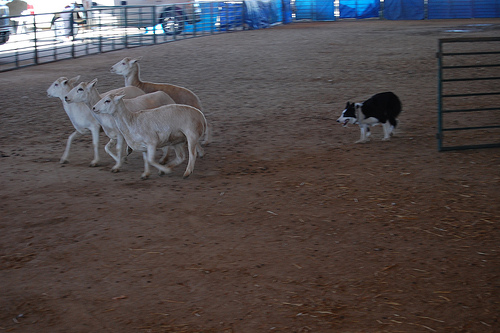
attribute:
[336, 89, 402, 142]
dog — black, white, compacted, herding sheep, herding, sheepdog, running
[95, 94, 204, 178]
sheep — running, in group, being herded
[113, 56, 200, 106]
sheep — tan, tall, in group, being herded, fenced in, running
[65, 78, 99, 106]
sheep — tan, in group, being herded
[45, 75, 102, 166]
sheep — tan, in group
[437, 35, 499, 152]
gate — open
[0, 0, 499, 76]
fence — metal, part of corral, black, blue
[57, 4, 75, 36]
man — in bright light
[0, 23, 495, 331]
ground — brown, dirt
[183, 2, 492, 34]
tarp — blue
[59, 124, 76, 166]
leg — slim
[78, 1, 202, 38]
truck — gray